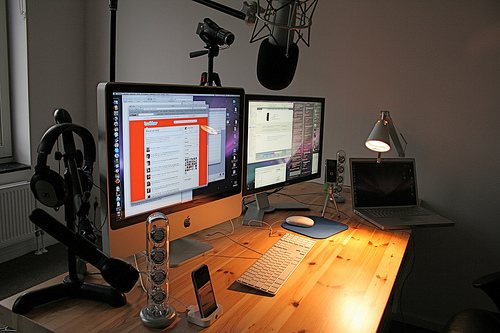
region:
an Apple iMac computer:
[96, 80, 246, 268]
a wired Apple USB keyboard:
[236, 228, 316, 298]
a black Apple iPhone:
[189, 263, 218, 320]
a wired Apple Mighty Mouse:
[283, 213, 315, 227]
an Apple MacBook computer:
[345, 150, 453, 230]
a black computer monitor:
[244, 91, 326, 223]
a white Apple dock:
[182, 301, 223, 326]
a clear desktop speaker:
[138, 210, 175, 326]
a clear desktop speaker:
[332, 147, 348, 204]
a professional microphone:
[246, 1, 318, 90]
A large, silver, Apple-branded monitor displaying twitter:
[97, 80, 243, 266]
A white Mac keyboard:
[236, 233, 311, 295]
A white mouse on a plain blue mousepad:
[280, 211, 347, 239]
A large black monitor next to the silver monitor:
[243, 93, 325, 226]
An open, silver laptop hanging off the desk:
[348, 155, 455, 230]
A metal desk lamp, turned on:
[365, 110, 408, 158]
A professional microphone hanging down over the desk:
[189, 0, 316, 91]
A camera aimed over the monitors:
[188, 18, 238, 87]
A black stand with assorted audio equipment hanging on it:
[11, 109, 127, 314]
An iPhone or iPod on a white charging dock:
[183, 263, 223, 326]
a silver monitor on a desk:
[97, 83, 244, 255]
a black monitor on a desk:
[246, 94, 326, 195]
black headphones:
[29, 121, 98, 208]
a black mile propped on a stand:
[29, 207, 137, 293]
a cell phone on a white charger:
[188, 263, 223, 326]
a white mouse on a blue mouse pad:
[282, 211, 347, 239]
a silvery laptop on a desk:
[348, 154, 455, 227]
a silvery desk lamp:
[364, 105, 409, 158]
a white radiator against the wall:
[1, 181, 48, 256]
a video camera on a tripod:
[189, 16, 234, 83]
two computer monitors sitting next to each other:
[92, 78, 342, 249]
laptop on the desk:
[337, 144, 447, 241]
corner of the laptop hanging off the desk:
[408, 203, 458, 233]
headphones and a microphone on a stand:
[3, 110, 140, 315]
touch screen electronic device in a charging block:
[175, 267, 229, 329]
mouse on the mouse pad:
[283, 211, 348, 239]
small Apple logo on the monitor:
[176, 214, 198, 232]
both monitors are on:
[97, 74, 327, 236]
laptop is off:
[347, 158, 444, 235]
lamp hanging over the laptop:
[360, 113, 418, 177]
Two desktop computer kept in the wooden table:
[97, 65, 328, 168]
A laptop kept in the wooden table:
[345, 155, 460, 239]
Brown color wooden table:
[330, 260, 408, 296]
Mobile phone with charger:
[190, 266, 235, 329]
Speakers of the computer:
[146, 213, 176, 325]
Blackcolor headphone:
[30, 117, 113, 192]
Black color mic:
[27, 205, 140, 292]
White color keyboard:
[235, 243, 317, 301]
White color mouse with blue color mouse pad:
[288, 205, 350, 229]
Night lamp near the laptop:
[368, 109, 418, 151]